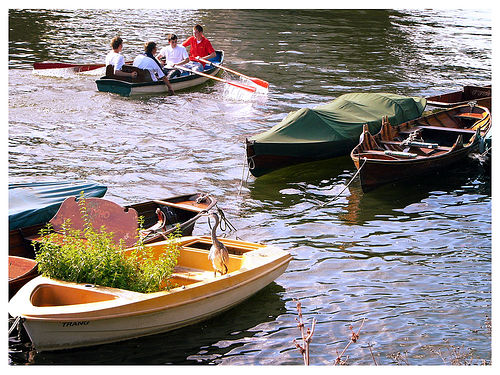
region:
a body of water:
[9, 9, 488, 362]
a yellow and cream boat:
[7, 235, 292, 352]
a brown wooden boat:
[343, 95, 493, 195]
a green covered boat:
[243, 91, 425, 178]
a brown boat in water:
[21, 184, 216, 262]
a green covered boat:
[2, 178, 107, 238]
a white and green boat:
[94, 42, 229, 97]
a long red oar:
[175, 63, 256, 97]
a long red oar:
[197, 52, 271, 89]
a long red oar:
[32, 58, 104, 71]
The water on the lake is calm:
[36, 97, 223, 182]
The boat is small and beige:
[16, 220, 326, 355]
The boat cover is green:
[248, 89, 426, 160]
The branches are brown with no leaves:
[287, 298, 491, 367]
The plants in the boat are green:
[31, 222, 183, 301]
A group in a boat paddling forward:
[23, 20, 273, 102]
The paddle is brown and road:
[186, 68, 258, 99]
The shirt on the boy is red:
[183, 22, 215, 65]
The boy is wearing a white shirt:
[158, 31, 188, 80]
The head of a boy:
[108, 30, 127, 53]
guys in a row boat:
[61, 13, 306, 105]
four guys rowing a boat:
[33, 15, 261, 130]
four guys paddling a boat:
[46, 17, 282, 112]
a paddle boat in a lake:
[43, 25, 285, 110]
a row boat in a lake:
[55, 23, 302, 121]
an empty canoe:
[363, 97, 497, 224]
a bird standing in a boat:
[187, 196, 262, 296]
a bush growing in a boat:
[35, 212, 208, 315]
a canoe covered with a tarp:
[245, 96, 433, 153]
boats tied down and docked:
[15, 104, 494, 345]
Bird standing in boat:
[200, 210, 232, 277]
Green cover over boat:
[240, 88, 432, 178]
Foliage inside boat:
[29, 190, 186, 295]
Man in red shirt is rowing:
[183, 23, 216, 68]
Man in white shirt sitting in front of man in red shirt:
[157, 33, 190, 75]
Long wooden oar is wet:
[196, 56, 271, 88]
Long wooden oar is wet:
[170, 62, 255, 95]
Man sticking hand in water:
[132, 40, 175, 95]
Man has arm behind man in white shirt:
[105, 34, 140, 82]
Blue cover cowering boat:
[5, 174, 107, 246]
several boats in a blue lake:
[5, 3, 499, 374]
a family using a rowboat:
[25, 19, 279, 104]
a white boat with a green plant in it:
[8, 208, 293, 364]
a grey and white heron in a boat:
[196, 210, 234, 277]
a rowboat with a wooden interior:
[351, 103, 491, 189]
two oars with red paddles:
[184, 55, 271, 93]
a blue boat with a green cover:
[237, 70, 429, 181]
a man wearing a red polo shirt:
[180, 25, 216, 61]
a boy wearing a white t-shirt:
[161, 33, 190, 73]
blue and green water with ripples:
[291, 187, 490, 362]